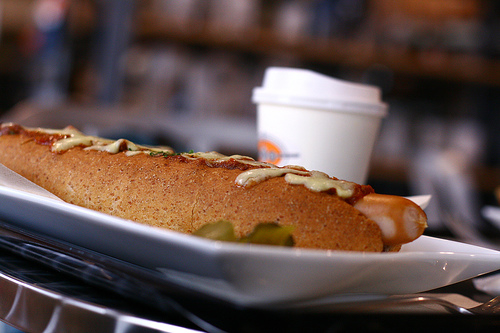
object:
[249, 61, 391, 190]
cup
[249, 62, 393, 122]
lid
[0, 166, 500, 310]
plate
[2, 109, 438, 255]
pizza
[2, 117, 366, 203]
cheese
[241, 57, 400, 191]
coffee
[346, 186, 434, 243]
hot dog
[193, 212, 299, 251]
pickles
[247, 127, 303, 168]
logo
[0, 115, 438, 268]
bread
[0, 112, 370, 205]
coverings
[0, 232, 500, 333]
countertop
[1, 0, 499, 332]
bar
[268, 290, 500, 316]
plate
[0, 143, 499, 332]
table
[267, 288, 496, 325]
silverware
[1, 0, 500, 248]
background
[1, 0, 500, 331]
restaurant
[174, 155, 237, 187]
crust